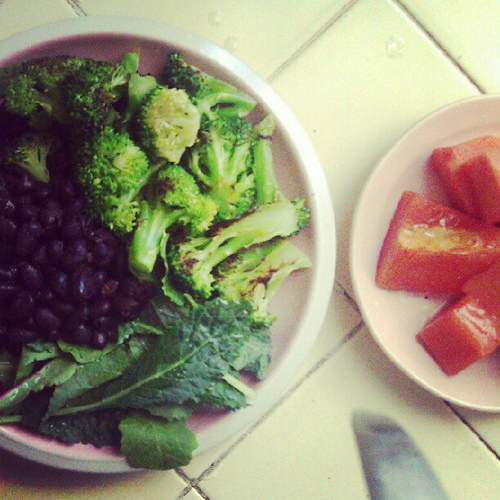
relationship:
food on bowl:
[414, 264, 499, 376] [347, 93, 499, 415]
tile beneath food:
[196, 317, 499, 499] [2, 48, 312, 323]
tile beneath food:
[196, 317, 499, 499] [0, 166, 162, 352]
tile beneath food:
[196, 317, 499, 499] [3, 302, 278, 469]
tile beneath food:
[196, 317, 499, 499] [374, 131, 499, 376]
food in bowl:
[1, 47, 312, 470] [3, 15, 339, 475]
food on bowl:
[430, 135, 499, 225] [347, 93, 499, 415]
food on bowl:
[375, 188, 499, 290] [347, 93, 499, 415]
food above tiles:
[8, 30, 492, 465] [0, 1, 499, 498]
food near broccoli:
[430, 135, 499, 225] [12, 48, 307, 425]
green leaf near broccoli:
[0, 297, 273, 470] [3, 48, 315, 325]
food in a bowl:
[166, 198, 300, 299] [3, 15, 339, 475]